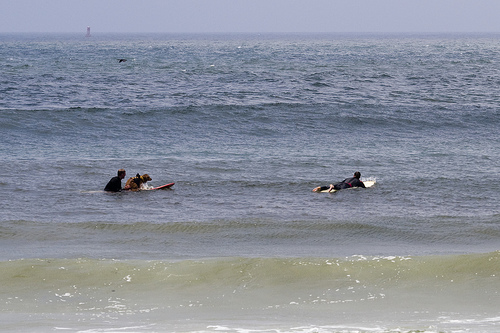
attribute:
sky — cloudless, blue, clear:
[0, 1, 499, 39]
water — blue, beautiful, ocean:
[0, 32, 499, 330]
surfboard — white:
[321, 178, 376, 194]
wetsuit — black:
[320, 178, 370, 190]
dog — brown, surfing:
[123, 172, 152, 191]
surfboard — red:
[137, 179, 175, 192]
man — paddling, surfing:
[310, 169, 368, 193]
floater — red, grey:
[84, 25, 92, 37]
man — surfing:
[102, 169, 127, 192]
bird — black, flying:
[111, 56, 129, 66]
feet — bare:
[309, 182, 337, 193]